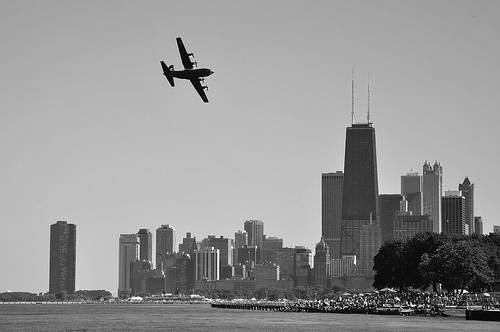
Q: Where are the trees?
A: Beside the dock.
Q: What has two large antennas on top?
A: Tall building.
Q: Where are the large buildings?
A: Near the water.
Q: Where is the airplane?
A: Above the lake.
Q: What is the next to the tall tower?
A: Shorter buildings.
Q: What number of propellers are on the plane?
A: Four.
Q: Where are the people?
A: On the pier.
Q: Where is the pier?
A: On the lake near the park.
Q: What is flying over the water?
A: Airplane.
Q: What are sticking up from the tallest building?
A: Antennas.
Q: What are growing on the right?
A: Trees.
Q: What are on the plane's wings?
A: Propellers.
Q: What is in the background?
A: Chicago skyline.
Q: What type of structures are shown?
A: Skyscrapers.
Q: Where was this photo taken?
A: Near the lake.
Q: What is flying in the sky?
A: Airplane.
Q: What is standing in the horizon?
A: Building.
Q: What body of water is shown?
A: An ocean.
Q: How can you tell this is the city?
A: Buildings.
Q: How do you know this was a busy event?
A: People on dock.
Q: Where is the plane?
A: In the sky.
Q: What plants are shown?
A: Trees.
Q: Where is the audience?
A: On the shore.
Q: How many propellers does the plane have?
A: Four.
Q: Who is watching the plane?
A: The audience.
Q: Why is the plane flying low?
A: An air show.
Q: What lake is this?
A: Lake Michigan.